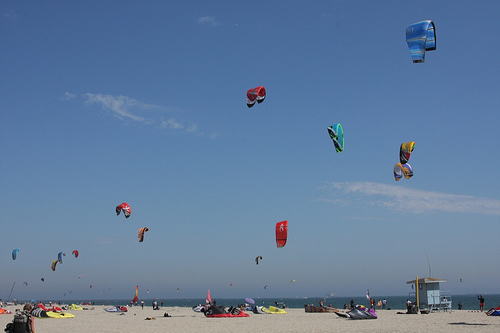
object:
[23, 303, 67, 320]
person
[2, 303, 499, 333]
beach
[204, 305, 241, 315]
person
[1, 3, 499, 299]
sky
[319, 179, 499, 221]
cloud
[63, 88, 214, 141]
cloud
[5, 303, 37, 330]
man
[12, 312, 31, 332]
backpack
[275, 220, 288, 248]
kite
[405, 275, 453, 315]
tower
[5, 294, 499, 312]
ocean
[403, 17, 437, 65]
kite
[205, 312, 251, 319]
towel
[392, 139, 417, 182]
kite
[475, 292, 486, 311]
man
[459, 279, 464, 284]
kite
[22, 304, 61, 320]
lady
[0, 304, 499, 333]
sand